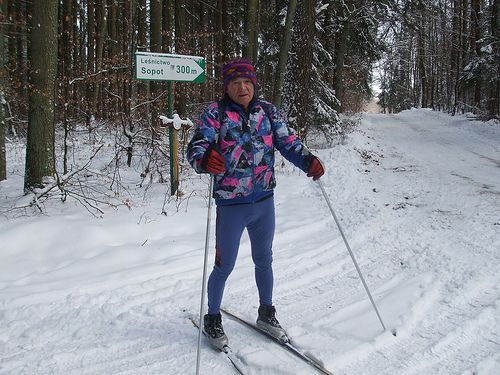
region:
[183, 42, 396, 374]
An older man in the foreground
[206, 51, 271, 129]
Man is wearing a knit cap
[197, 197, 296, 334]
Man is wearing tight pants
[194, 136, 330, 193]
Man is wearing red gloves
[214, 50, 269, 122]
Man is looking at the camera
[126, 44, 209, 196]
A sign in the background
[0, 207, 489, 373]
Tracks are in the snow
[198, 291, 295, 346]
Man is wearing black shoes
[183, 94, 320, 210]
Man is wearing a coat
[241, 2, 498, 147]
Snow is covering the trees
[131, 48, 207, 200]
a white and green sign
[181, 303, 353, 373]
a pair of skis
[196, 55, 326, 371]
an old man is in the snow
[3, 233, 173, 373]
white snow on the ground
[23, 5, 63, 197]
the brown trunk of a tree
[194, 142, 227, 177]
a red and black glove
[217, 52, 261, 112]
a man wearing a ski cap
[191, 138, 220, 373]
a handheld ski pole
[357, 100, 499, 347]
a snow covered path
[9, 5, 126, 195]
a forest full of trees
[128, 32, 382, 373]
person standing on skis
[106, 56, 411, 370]
person standing on snow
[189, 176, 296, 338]
pair of purple leggings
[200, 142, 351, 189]
pair of red gloves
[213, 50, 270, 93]
a multicolored purple hat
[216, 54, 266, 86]
pink design on hat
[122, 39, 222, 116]
green and white sign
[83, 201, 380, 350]
ski tracks in snow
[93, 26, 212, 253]
Roadsign to nearest town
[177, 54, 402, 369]
Colorful Skiier Posing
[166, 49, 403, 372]
Older man in ski gear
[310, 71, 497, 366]
Snowy roadway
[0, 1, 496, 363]
Older Skiier posing in front of snowy woods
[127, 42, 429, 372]
Elderly Skiier Taking a break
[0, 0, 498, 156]
Snowy wooded area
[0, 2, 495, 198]
Winter Wooded area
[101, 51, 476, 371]
Colorful old skier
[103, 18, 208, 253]
Navigational Marker in the snow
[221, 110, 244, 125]
The patch is pink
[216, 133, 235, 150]
The patch is pink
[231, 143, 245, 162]
The patch is pink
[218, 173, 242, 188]
The patch is pink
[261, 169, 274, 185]
The patch is pink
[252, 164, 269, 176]
The patch is pink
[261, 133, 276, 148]
The patch is pink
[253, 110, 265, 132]
The patch is pink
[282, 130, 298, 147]
The patch is pink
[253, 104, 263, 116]
The patch is pink